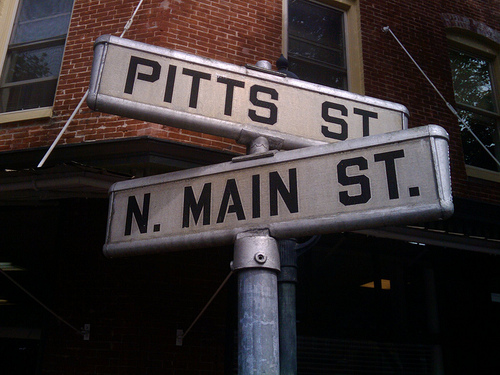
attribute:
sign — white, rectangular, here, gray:
[101, 123, 457, 258]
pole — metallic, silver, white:
[233, 228, 282, 374]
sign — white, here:
[87, 34, 409, 155]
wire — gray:
[382, 24, 499, 168]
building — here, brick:
[0, 0, 499, 203]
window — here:
[282, 1, 349, 94]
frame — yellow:
[280, 1, 365, 98]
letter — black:
[125, 194, 151, 237]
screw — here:
[254, 251, 266, 264]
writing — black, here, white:
[125, 150, 422, 236]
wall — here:
[0, 0, 499, 208]